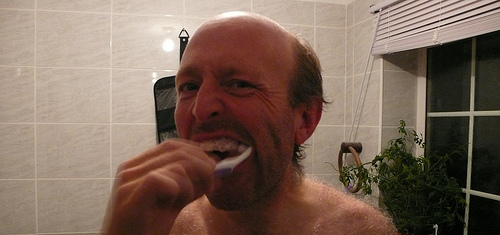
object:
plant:
[333, 115, 470, 233]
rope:
[346, 24, 381, 182]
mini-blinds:
[368, 3, 497, 58]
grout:
[17, 63, 71, 128]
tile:
[0, 0, 182, 229]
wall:
[5, 5, 382, 225]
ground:
[436, 149, 455, 151]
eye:
[177, 79, 197, 92]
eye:
[229, 76, 253, 89]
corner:
[334, 4, 382, 195]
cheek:
[230, 93, 292, 173]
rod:
[351, 53, 377, 148]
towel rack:
[341, 143, 364, 190]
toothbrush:
[200, 145, 258, 177]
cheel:
[244, 120, 290, 177]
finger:
[111, 140, 228, 202]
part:
[280, 185, 301, 211]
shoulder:
[290, 161, 399, 233]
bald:
[172, 9, 293, 59]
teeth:
[193, 136, 251, 163]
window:
[382, 0, 497, 233]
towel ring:
[335, 140, 367, 193]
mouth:
[183, 132, 257, 175]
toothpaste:
[189, 137, 243, 156]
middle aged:
[97, 12, 397, 234]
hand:
[69, 131, 236, 209]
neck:
[167, 167, 350, 227]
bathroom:
[0, 1, 499, 231]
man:
[95, 12, 397, 232]